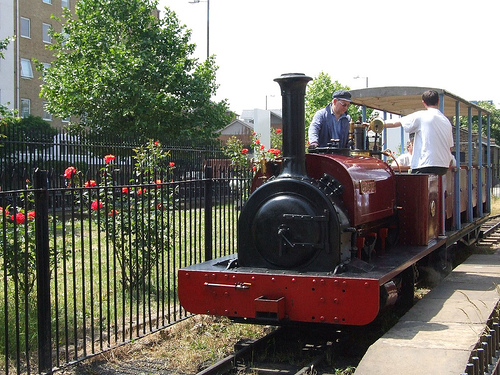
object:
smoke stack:
[271, 71, 314, 180]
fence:
[0, 165, 242, 375]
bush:
[58, 138, 182, 293]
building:
[0, 0, 164, 198]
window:
[15, 14, 31, 39]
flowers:
[62, 165, 75, 180]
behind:
[1, 117, 261, 375]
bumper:
[177, 268, 379, 327]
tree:
[30, 0, 237, 213]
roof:
[333, 86, 494, 120]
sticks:
[452, 108, 493, 228]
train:
[172, 71, 499, 329]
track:
[201, 324, 365, 375]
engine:
[176, 72, 429, 328]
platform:
[350, 241, 500, 375]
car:
[339, 85, 493, 247]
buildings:
[2, 0, 252, 208]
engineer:
[307, 89, 353, 152]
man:
[360, 90, 456, 175]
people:
[444, 141, 461, 168]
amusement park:
[1, 0, 500, 375]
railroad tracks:
[177, 210, 500, 375]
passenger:
[388, 137, 420, 169]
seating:
[438, 165, 488, 221]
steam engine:
[234, 71, 398, 270]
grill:
[176, 269, 380, 327]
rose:
[100, 156, 114, 165]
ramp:
[353, 247, 500, 375]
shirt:
[397, 107, 457, 170]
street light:
[186, 0, 212, 176]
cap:
[330, 87, 352, 100]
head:
[327, 90, 350, 118]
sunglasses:
[329, 98, 354, 103]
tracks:
[176, 216, 499, 375]